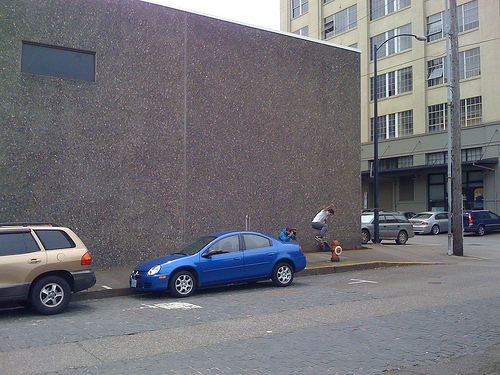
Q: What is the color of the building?
A: Brown.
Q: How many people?
A: 2.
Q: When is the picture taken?
A: Daytime.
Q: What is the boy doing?
A: Skating.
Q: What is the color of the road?
A: Grey.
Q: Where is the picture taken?
A: On a city street.